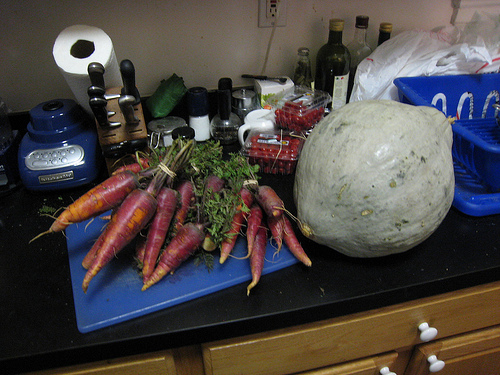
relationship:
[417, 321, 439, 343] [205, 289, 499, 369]
handle on drawer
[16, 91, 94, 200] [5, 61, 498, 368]
base on counter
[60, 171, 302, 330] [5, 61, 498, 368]
cutting board on counter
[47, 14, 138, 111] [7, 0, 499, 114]
roll near wall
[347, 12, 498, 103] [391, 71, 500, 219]
bags behind dish drainer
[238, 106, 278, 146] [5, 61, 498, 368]
mug on counter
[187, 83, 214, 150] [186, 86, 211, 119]
shaker with top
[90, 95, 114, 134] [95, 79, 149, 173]
knife in knife rack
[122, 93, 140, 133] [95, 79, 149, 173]
knife in knife rack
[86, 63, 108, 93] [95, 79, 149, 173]
knife in knife rack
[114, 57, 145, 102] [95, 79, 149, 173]
knife in knife rack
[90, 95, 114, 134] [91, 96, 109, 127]
knife has handle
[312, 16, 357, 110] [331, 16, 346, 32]
bottle has cap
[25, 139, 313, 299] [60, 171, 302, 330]
vegetables on cutting board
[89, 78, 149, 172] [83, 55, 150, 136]
block has knives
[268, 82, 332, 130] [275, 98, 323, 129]
box of tomatoes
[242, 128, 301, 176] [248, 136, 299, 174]
box of tomatoes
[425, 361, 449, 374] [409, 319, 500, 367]
handle on cupboard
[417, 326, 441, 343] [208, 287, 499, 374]
handle on cupboard